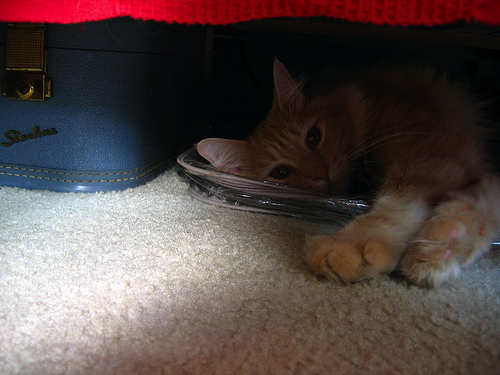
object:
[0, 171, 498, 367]
carpet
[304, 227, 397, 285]
paws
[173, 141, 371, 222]
bag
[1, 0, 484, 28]
cloth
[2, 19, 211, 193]
luggage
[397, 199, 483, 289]
paw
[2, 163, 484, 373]
surface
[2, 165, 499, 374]
floor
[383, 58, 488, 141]
body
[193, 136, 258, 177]
ear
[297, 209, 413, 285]
paw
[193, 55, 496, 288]
cat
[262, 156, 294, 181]
eye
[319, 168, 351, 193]
mouth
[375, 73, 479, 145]
hair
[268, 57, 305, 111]
ear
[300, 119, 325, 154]
eye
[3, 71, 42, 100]
buckle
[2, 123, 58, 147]
word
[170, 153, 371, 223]
plastic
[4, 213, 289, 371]
carpet